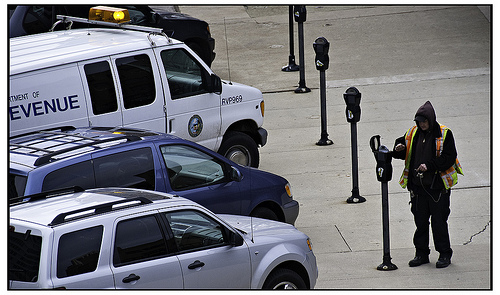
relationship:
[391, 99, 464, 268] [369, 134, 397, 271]
man checking meter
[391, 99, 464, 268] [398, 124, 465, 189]
man wearing vest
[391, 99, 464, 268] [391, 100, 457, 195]
man has hoodie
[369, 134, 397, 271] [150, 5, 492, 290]
meter on sidewalk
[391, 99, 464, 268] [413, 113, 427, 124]
man wearing cap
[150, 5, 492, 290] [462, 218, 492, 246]
sidewalk has crack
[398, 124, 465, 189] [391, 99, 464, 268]
vest on man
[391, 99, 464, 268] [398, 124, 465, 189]
man has vest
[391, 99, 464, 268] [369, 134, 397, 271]
man by meter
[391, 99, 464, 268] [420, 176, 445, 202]
man has chain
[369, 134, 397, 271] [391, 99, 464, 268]
meter by man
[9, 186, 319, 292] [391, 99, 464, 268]
vehicle by man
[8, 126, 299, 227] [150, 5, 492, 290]
van by sidewalk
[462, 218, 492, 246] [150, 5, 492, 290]
crack in sidewalk